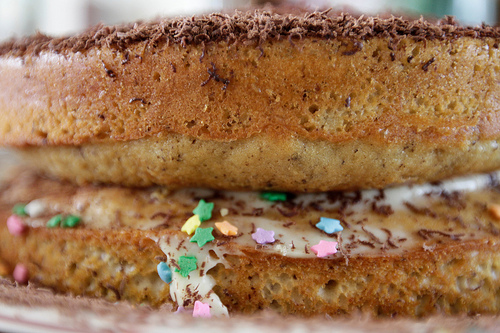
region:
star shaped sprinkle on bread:
[248, 220, 281, 251]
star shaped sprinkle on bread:
[176, 209, 201, 234]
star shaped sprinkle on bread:
[189, 226, 216, 251]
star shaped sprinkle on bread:
[174, 257, 208, 271]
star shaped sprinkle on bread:
[156, 260, 173, 280]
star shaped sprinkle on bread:
[186, 298, 223, 319]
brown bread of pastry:
[13, 165, 498, 331]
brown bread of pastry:
[3, 15, 490, 162]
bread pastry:
[5, 22, 474, 313]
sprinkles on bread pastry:
[88, 77, 413, 314]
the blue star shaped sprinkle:
[315, 215, 342, 233]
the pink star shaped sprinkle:
[313, 240, 336, 255]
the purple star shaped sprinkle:
[251, 227, 273, 243]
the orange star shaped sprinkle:
[213, 219, 237, 236]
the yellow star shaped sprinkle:
[180, 214, 200, 234]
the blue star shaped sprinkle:
[155, 261, 171, 283]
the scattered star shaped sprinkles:
[6, 192, 344, 321]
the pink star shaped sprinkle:
[191, 299, 210, 315]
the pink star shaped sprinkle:
[6, 216, 21, 235]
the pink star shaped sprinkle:
[12, 262, 27, 282]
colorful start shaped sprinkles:
[154, 190, 237, 300]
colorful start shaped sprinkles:
[261, 212, 345, 257]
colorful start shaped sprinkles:
[5, 201, 70, 227]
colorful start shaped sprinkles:
[186, 194, 235, 251]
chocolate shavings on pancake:
[12, 11, 497, 75]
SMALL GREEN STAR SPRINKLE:
[193, 191, 215, 212]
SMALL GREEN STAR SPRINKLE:
[191, 225, 216, 246]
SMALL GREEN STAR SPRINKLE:
[173, 252, 210, 283]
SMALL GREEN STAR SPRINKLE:
[45, 212, 60, 234]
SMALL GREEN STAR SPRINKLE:
[62, 207, 89, 233]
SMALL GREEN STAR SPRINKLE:
[263, 191, 288, 205]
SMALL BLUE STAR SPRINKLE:
[316, 202, 363, 237]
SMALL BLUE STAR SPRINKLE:
[138, 254, 170, 279]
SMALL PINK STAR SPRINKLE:
[311, 236, 356, 270]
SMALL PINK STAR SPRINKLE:
[186, 299, 223, 323]